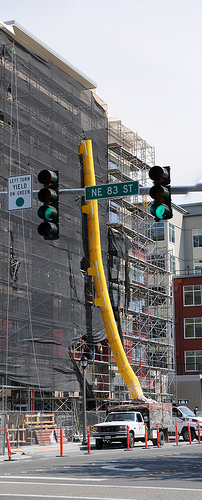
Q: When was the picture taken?
A: In the daytime.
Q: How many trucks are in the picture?
A: Two.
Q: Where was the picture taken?
A: At a construction site.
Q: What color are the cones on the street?
A: Orange.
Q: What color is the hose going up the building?
A: Yellow.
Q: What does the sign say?
A: NE 83 ST.